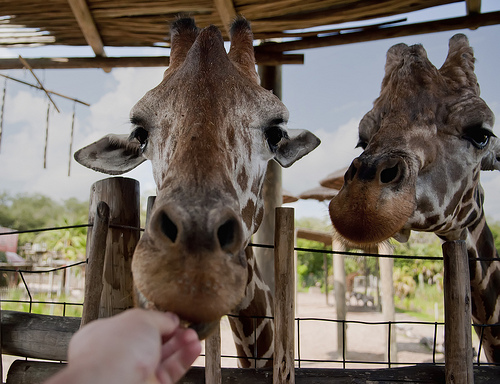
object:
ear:
[72, 132, 147, 175]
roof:
[0, 0, 500, 69]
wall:
[433, 238, 499, 381]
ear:
[273, 128, 320, 167]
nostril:
[216, 215, 243, 254]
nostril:
[151, 206, 185, 245]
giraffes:
[325, 33, 498, 365]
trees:
[47, 197, 91, 256]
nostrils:
[377, 158, 402, 185]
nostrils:
[345, 158, 360, 185]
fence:
[331, 238, 435, 383]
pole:
[273, 205, 294, 382]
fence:
[202, 205, 377, 383]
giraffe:
[73, 15, 319, 369]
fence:
[0, 175, 115, 382]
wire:
[340, 318, 346, 371]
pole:
[84, 175, 139, 382]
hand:
[67, 307, 202, 383]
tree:
[0, 195, 62, 232]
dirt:
[314, 367, 354, 383]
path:
[190, 232, 488, 370]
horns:
[157, 15, 264, 83]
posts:
[441, 238, 472, 382]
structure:
[0, 15, 148, 48]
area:
[0, 193, 499, 381]